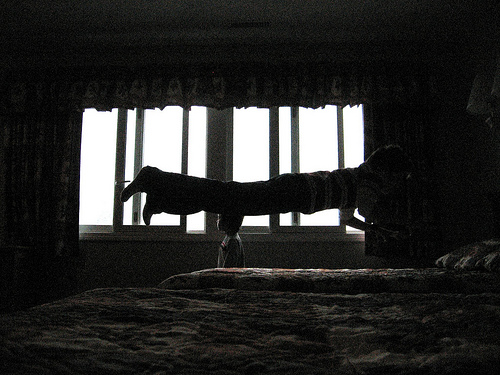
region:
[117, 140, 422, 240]
The man appears to be flying in the air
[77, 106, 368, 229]
Light is coming through the windows.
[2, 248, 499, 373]
Two beds are next to each other.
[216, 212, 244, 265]
A boy is standing and looking to the left.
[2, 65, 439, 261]
The window has ruffled curtains around it.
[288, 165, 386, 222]
The man is wearing a striped shirt.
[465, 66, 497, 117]
The lamp shade is angled back at the top.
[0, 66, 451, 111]
A valance is over the window.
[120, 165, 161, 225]
The feet do not have shoes on.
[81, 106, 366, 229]
The windows have different size spacing in the vertical strips and may be open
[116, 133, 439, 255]
little boy in the air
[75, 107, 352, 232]
light coming in the windows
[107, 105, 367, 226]
lines on the windows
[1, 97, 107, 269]
curtains pushed to ones side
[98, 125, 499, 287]
kid hovering over a bed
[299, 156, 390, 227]
striped short sleeved shirt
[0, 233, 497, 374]
two beds that are both made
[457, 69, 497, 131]
lamp on the wall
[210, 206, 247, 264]
little boy standing by the window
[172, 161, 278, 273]
little boy looking out the window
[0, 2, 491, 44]
ceiling in a bedroom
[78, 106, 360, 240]
windows allowing light in room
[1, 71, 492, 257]
curtains covering window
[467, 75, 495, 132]
lamps in bedroom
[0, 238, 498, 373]
two beds in a room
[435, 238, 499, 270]
pillows sitting on bed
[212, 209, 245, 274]
boy standing on floor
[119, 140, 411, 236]
boy bouncing on bed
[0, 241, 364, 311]
wall on opposite side of room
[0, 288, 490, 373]
floral blanket on bed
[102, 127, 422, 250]
child leaping onto bed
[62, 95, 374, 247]
windows behind boy leaping on bed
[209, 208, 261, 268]
child walking in front of windows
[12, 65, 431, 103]
valance over top of windows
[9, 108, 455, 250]
curtains on either side of window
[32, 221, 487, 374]
two beds in room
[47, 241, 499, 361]
bedspreads on the beds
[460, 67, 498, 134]
lamp attached to the wall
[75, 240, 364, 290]
wall below the windows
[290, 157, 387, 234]
striped shirt of boy leaping onto bed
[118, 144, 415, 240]
A boy in mid air over a bed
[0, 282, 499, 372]
A bed a boy is about to fall onto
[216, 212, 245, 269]
A boy standing up past the beds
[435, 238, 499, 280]
Pillows on the bed behind a standing boy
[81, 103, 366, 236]
Large windows in the room with light coming through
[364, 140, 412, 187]
Head of a boy with short hair who is in the air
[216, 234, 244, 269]
Long sleeve shirt on a standing boy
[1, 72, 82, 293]
Dark curtain to the left of the window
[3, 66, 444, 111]
A short valance that goes across the whole window at the top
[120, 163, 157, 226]
Feet of a boy in mid air